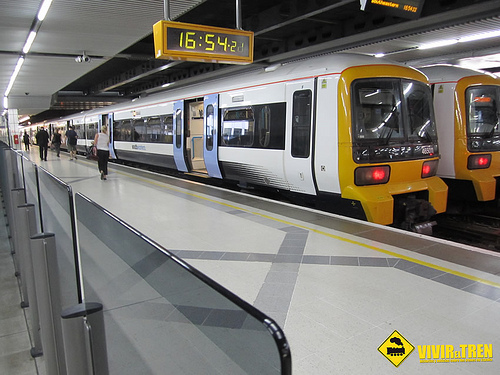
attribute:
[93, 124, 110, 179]
woman — walking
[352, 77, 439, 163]
window — large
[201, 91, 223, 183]
door — blue, open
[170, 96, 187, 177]
door — open, blue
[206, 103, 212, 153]
window — oval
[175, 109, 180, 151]
window — oval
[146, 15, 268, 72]
sign — yellow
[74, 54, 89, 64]
camera — security camera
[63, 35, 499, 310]
trains/station — white, yellow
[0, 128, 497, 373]
platform — gray, yellow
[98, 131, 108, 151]
shirt — sleeveless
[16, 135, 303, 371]
glass panels — tinted